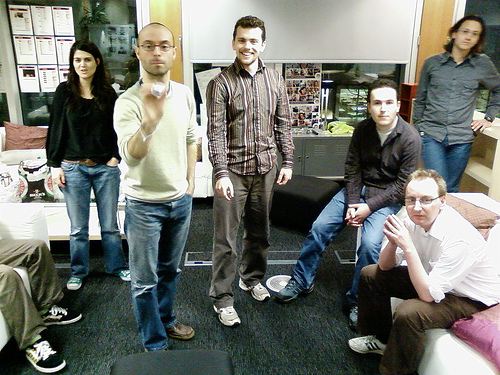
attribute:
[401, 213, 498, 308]
shirt —  button down,  white,  man's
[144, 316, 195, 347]
shoes — brown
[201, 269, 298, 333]
footwear —  man's,   white ,  athletic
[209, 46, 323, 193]
shirt —  brown and red 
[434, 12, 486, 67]
brown hair —  long,  brown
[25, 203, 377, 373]
green carpet —  dark green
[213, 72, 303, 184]
shirt striped —  striped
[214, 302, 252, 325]
shoes —  grey and white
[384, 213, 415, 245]
hand —  his,  folded 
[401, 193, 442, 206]
glasses —  thin 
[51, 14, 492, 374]
people —  very relaxed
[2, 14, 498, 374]
people —  inside,  friends and coworkers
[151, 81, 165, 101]
controller — of wii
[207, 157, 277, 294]
pants —  brown  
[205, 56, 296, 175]
shirt —  collared